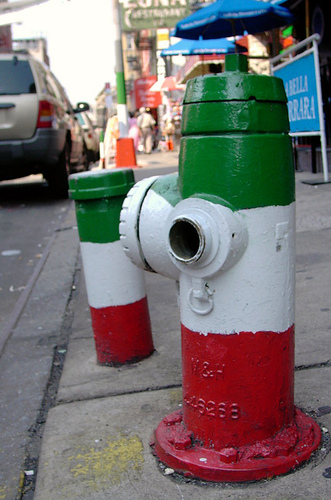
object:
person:
[134, 100, 156, 155]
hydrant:
[115, 39, 330, 492]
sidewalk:
[41, 127, 331, 499]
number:
[229, 400, 241, 422]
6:
[217, 400, 228, 421]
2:
[205, 398, 216, 419]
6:
[197, 397, 205, 417]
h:
[213, 363, 227, 384]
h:
[190, 357, 199, 377]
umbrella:
[171, 0, 290, 45]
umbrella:
[158, 34, 248, 60]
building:
[257, 0, 331, 171]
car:
[74, 102, 102, 163]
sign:
[270, 36, 326, 152]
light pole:
[110, 0, 131, 142]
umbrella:
[146, 71, 189, 97]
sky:
[5, 4, 129, 107]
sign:
[132, 73, 163, 110]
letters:
[140, 96, 144, 103]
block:
[110, 133, 141, 169]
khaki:
[141, 130, 152, 147]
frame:
[257, 34, 329, 183]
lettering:
[302, 94, 311, 119]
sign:
[114, 1, 201, 30]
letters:
[158, 2, 168, 29]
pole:
[65, 160, 155, 372]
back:
[0, 52, 46, 167]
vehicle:
[0, 46, 89, 205]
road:
[0, 160, 84, 500]